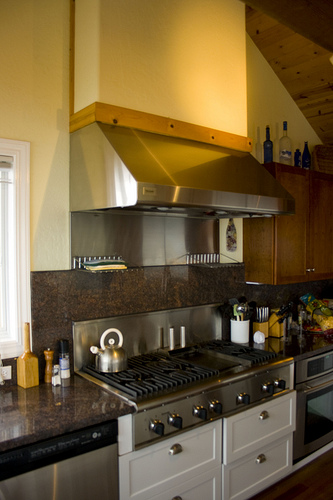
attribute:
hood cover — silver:
[66, 119, 294, 218]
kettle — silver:
[81, 322, 130, 375]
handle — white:
[97, 322, 127, 351]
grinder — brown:
[37, 341, 57, 384]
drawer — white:
[212, 387, 302, 460]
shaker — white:
[47, 366, 66, 389]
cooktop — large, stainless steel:
[70, 303, 304, 455]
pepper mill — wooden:
[38, 343, 58, 382]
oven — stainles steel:
[287, 353, 330, 463]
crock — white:
[231, 317, 252, 344]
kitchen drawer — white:
[220, 385, 297, 461]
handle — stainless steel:
[259, 407, 269, 420]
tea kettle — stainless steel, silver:
[87, 323, 131, 374]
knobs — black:
[140, 376, 290, 438]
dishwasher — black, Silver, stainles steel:
[1, 418, 121, 498]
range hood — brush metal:
[70, 118, 293, 213]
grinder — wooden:
[43, 344, 52, 386]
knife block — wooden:
[258, 313, 285, 343]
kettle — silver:
[86, 323, 127, 375]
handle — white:
[96, 325, 122, 349]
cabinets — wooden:
[248, 161, 331, 286]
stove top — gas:
[77, 335, 296, 408]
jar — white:
[228, 318, 251, 345]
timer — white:
[249, 329, 268, 348]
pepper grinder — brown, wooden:
[44, 346, 54, 385]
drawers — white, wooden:
[118, 389, 299, 497]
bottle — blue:
[258, 118, 277, 164]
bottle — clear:
[273, 115, 296, 164]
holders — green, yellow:
[80, 253, 129, 278]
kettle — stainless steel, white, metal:
[84, 324, 126, 376]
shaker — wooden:
[40, 344, 54, 385]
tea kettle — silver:
[87, 325, 128, 371]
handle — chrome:
[167, 442, 180, 454]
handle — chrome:
[260, 409, 268, 419]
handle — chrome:
[255, 454, 267, 463]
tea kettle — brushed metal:
[89, 327, 127, 372]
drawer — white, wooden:
[218, 393, 300, 463]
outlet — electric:
[1, 362, 19, 385]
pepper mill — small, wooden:
[42, 345, 58, 387]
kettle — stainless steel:
[85, 321, 132, 374]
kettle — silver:
[89, 328, 125, 372]